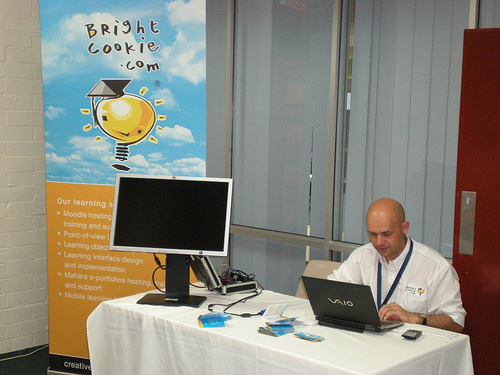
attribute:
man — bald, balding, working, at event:
[330, 196, 464, 333]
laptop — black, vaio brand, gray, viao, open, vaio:
[302, 274, 401, 332]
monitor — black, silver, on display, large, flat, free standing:
[111, 172, 234, 309]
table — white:
[77, 276, 470, 373]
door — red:
[453, 29, 500, 374]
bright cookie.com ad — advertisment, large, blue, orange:
[38, 3, 213, 375]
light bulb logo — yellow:
[81, 94, 165, 166]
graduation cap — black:
[88, 76, 130, 103]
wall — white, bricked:
[1, 2, 50, 353]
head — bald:
[364, 197, 409, 259]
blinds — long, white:
[235, 3, 459, 309]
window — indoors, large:
[230, 3, 470, 317]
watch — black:
[417, 312, 428, 325]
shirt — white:
[329, 239, 465, 327]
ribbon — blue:
[374, 237, 413, 315]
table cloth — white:
[86, 273, 472, 373]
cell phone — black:
[403, 326, 422, 340]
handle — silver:
[457, 190, 475, 257]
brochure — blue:
[198, 309, 225, 327]